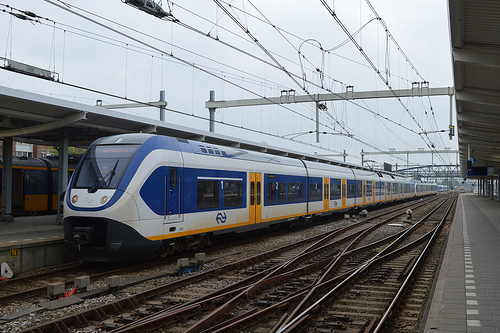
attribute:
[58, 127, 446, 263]
train — striped, colorful, blue, metal, yellow, long, stopped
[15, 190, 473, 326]
track — numerous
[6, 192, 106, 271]
platform — gray, empty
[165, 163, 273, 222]
door — yellow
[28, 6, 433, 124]
sky — overcast